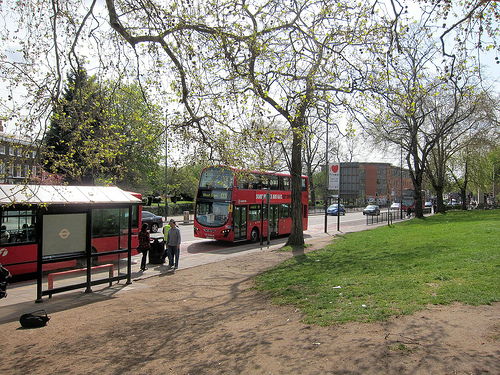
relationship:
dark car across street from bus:
[134, 208, 166, 233] [188, 156, 325, 247]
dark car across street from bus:
[134, 208, 166, 233] [0, 175, 145, 277]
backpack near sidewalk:
[13, 309, 59, 336] [15, 245, 187, 313]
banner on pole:
[327, 164, 342, 193] [334, 164, 344, 234]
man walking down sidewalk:
[165, 220, 183, 270] [4, 242, 280, 265]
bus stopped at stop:
[165, 116, 347, 251] [2, 178, 146, 300]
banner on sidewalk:
[327, 164, 342, 193] [175, 229, 303, 254]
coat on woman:
[138, 230, 155, 252] [137, 222, 160, 274]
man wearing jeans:
[165, 220, 183, 270] [159, 243, 204, 269]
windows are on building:
[338, 163, 361, 195] [314, 160, 418, 207]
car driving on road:
[359, 202, 384, 222] [6, 204, 447, 267]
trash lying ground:
[330, 283, 343, 294] [263, 248, 498, 321]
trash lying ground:
[358, 297, 368, 309] [263, 248, 498, 321]